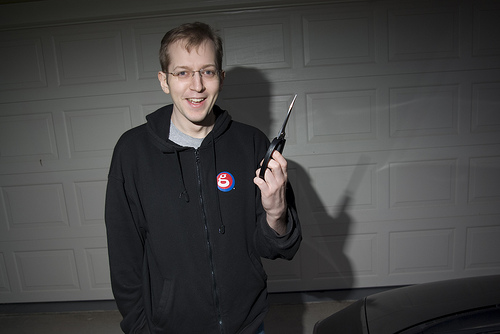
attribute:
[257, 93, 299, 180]
scissors — black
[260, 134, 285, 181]
handle — black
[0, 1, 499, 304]
garage door — white, paneled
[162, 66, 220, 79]
glasses — silver rimmed, thin framed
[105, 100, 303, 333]
hoodie — black, dark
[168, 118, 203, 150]
shirt — grey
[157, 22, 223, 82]
hair — blonde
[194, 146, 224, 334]
zipper — black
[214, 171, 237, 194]
logo — red, blue, red white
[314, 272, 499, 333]
car — black